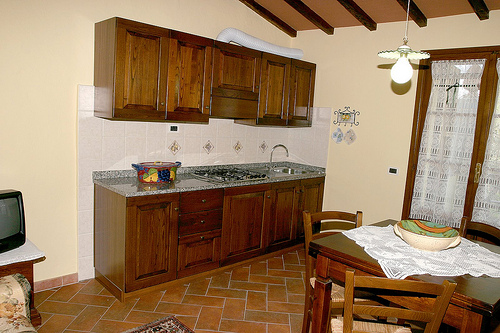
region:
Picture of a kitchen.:
[51, 8, 479, 325]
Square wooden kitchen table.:
[317, 192, 499, 314]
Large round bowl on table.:
[385, 212, 472, 257]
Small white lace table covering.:
[347, 216, 497, 282]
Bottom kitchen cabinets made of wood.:
[85, 161, 322, 288]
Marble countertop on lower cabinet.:
[87, 162, 326, 192]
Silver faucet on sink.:
[263, 140, 306, 180]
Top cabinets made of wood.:
[93, 6, 324, 131]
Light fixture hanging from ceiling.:
[381, 33, 433, 92]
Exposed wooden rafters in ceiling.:
[252, 4, 491, 35]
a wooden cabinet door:
[61, 12, 171, 144]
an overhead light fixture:
[381, 26, 446, 106]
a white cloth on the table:
[343, 215, 495, 289]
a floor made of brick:
[171, 287, 313, 327]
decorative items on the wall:
[326, 100, 385, 152]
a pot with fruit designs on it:
[118, 162, 200, 184]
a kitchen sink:
[258, 147, 315, 194]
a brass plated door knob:
[461, 142, 493, 192]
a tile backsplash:
[63, 110, 260, 162]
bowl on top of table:
[393, 204, 465, 260]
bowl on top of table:
[305, 187, 497, 331]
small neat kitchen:
[79, 56, 434, 296]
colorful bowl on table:
[381, 218, 475, 274]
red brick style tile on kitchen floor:
[217, 276, 282, 316]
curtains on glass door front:
[434, 41, 469, 219]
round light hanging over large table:
[368, 16, 441, 110]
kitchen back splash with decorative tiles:
[154, 129, 258, 162]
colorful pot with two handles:
[108, 154, 202, 193]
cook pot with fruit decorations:
[117, 160, 214, 187]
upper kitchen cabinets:
[86, 18, 310, 136]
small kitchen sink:
[252, 136, 313, 178]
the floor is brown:
[202, 276, 294, 315]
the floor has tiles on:
[206, 287, 290, 324]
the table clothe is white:
[297, 206, 489, 274]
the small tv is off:
[0, 191, 33, 247]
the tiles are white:
[92, 128, 279, 148]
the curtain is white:
[428, 110, 468, 211]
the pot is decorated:
[121, 159, 196, 178]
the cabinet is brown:
[112, 90, 312, 136]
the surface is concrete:
[255, 158, 302, 176]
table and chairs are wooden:
[299, 217, 489, 302]